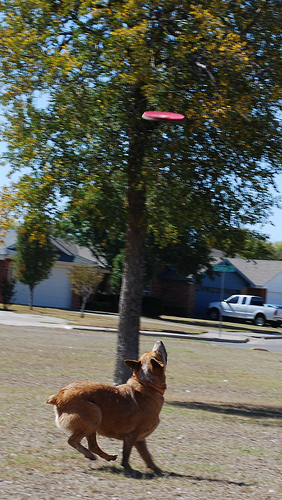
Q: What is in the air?
A: Frisbee.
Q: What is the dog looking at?
A: Frisbee.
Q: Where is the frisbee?
A: In the air.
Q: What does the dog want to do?
A: Catch Frisbee.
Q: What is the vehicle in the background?
A: Truck.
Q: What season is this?
A: Summer.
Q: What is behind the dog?
A: Tree.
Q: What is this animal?
A: Dog.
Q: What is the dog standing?
A: Grass.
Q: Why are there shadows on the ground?
A: Sun is shining.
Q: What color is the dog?
A: Brown.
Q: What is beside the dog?
A: Tree.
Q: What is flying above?
A: Frisbee.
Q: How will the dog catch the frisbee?
A: Jumping.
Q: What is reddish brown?
A: The dog.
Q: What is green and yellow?
A: Leaves.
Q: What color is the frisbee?
A: Pink.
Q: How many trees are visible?
A: 4.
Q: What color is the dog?
A: Brown.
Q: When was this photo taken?
A: During the day.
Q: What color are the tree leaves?
A: Green.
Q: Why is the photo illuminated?
A: Sunlight.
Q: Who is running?
A: The dog.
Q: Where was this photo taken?
A: At the park.